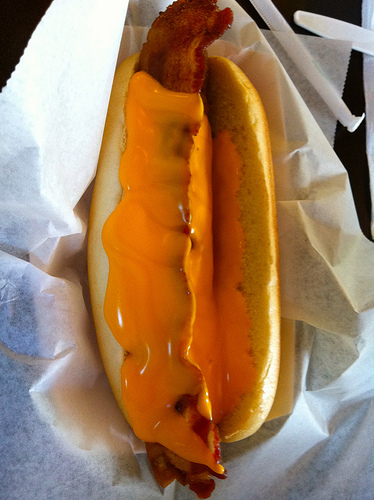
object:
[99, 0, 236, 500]
hotdog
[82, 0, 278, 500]
top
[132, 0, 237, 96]
bacon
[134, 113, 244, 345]
cheese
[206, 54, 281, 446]
bun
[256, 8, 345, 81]
straw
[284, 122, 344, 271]
crinkled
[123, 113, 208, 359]
bright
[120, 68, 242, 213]
strips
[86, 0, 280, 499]
toasty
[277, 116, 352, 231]
white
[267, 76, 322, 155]
paper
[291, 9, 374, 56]
handle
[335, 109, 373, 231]
black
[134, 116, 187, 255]
orange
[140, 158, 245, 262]
melted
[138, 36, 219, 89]
end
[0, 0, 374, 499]
black table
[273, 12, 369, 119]
corner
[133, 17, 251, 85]
other end